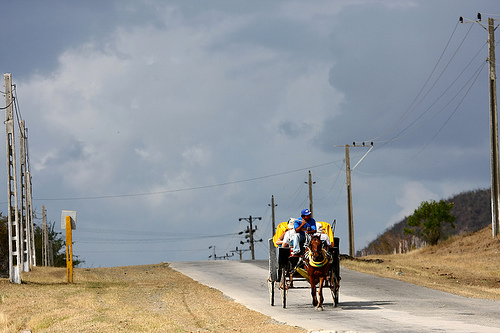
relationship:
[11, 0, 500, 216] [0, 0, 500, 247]
cloud in clouds sky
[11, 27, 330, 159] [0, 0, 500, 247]
cloud in clouds sky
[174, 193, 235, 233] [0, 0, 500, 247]
clouds sky in clouds sky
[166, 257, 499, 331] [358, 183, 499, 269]
road on hillside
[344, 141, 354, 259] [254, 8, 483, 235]
pole for electrical line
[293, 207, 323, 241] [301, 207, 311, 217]
man wearing hat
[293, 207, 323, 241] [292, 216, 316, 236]
man wearing shirt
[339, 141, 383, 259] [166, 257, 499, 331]
pole on road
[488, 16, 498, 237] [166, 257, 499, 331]
pole on road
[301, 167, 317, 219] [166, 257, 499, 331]
pole on road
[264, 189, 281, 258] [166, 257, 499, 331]
pole on road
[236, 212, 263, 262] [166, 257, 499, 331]
pole on road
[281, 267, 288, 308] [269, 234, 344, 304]
wheel on a cart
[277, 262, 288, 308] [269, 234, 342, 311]
wheel on a cart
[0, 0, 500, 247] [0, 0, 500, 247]
clouds sky in clouds sky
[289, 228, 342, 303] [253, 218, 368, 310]
horse pulling wagon